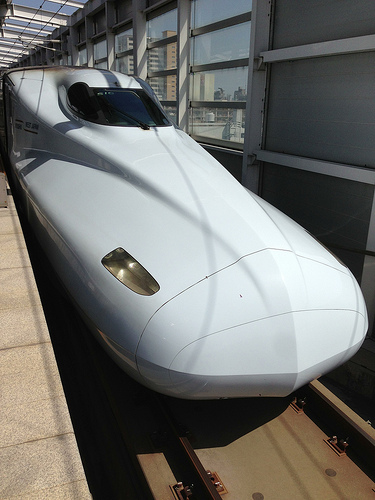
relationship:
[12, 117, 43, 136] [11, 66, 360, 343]
name of train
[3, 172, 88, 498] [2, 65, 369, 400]
tiles beside train batmobile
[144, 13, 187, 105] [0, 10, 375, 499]
window in a station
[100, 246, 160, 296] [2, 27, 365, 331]
headlight on white vehicle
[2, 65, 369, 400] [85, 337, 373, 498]
batmobile of tracks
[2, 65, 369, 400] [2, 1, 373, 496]
batmobile in station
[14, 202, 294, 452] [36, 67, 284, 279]
shadow of train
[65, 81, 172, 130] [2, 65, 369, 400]
window in front of batmobile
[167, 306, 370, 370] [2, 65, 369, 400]
line in front of batmobile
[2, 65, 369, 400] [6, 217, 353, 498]
batmobile on track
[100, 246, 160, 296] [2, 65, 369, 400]
headlight on batmobile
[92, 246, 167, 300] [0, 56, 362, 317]
headlight on train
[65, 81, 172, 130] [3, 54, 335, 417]
window on batmobile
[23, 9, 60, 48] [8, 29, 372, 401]
wires power train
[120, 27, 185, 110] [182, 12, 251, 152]
building outside window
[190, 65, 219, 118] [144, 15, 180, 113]
building outside window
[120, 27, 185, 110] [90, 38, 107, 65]
building outside window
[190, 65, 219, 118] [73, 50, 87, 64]
building outside window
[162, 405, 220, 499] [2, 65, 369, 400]
metal rail beneath batmobile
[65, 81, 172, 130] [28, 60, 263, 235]
window of train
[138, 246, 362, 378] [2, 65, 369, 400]
grooves on front of batmobile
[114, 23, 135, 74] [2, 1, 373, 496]
window in a station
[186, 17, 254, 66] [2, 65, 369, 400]
window in a batmobile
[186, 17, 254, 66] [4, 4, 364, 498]
window in a train station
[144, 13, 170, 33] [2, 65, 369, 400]
window in a batmobile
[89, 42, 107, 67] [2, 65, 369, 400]
window in a batmobile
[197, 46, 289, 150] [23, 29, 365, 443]
window in a train station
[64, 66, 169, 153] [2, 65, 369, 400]
window of batmobile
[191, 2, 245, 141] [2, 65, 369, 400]
window of batmobile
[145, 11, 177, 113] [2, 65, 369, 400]
window of batmobile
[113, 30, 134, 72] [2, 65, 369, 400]
window of batmobile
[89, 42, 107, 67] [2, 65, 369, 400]
window of batmobile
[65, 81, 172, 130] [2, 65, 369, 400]
window to right of batmobile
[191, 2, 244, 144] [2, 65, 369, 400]
windows to right of batmobile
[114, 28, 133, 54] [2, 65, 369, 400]
window to right of batmobile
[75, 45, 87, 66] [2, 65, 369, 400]
windows to right of batmobile